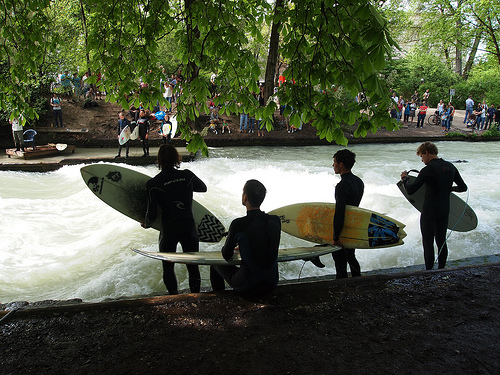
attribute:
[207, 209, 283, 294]
wet suit — black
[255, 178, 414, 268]
surfboard — white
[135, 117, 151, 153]
wetsuit — black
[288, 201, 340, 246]
surfboard — yellow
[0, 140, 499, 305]
water — Rushing, white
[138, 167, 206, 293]
wetsuits — black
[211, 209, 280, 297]
wetsuits — black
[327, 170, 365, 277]
wetsuits — black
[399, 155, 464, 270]
wetsuits — black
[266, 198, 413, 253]
surfboard — yellow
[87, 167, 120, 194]
designs — black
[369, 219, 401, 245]
flower — blue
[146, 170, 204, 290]
wetsuit — black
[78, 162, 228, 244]
surfboard — white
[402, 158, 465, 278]
wetsuit — black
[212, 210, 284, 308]
wetsuit — black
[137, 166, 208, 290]
wetsuit — black